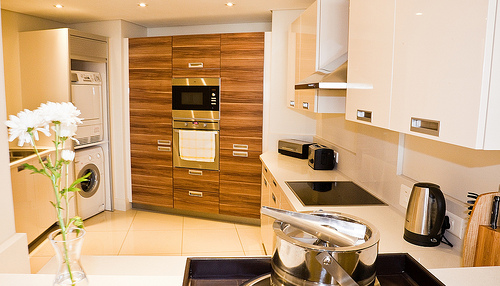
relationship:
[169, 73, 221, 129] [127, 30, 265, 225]
oven in wall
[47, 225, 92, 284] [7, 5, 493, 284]
vessel in room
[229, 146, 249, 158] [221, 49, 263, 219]
handle has door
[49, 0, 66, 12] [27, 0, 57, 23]
light bulb in ceiling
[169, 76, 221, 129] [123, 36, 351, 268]
oven in wall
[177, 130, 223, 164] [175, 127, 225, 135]
towel hanging from handle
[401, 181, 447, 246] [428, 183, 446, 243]
pot with handle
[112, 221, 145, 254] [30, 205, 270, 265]
floor has tiles